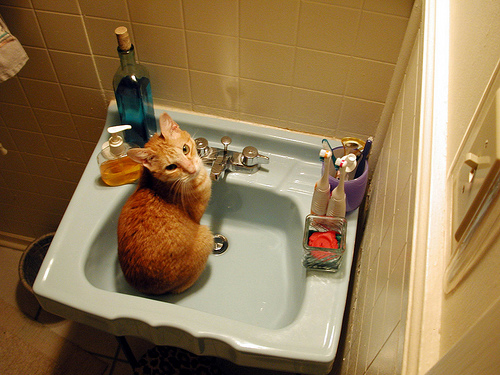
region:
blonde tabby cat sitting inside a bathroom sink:
[117, 111, 212, 296]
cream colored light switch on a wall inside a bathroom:
[455, 98, 496, 240]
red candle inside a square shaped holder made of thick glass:
[302, 212, 347, 272]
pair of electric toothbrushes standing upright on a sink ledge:
[311, 149, 346, 228]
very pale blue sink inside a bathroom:
[31, 96, 364, 372]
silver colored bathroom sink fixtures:
[191, 135, 269, 181]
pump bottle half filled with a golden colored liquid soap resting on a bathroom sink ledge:
[97, 123, 144, 185]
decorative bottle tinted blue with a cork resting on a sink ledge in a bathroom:
[111, 25, 156, 148]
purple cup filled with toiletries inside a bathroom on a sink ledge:
[321, 145, 370, 215]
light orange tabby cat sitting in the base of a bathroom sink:
[116, 111, 211, 296]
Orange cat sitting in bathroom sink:
[114, 112, 216, 297]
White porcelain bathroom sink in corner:
[31, 94, 371, 372]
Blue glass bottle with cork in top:
[111, 24, 158, 151]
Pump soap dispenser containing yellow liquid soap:
[96, 122, 146, 186]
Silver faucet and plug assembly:
[192, 135, 271, 184]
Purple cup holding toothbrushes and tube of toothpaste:
[320, 145, 370, 215]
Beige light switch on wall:
[453, 86, 499, 241]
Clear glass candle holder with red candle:
[301, 213, 349, 274]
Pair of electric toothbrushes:
[310, 148, 349, 220]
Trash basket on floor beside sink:
[18, 228, 58, 296]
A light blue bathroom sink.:
[31, 92, 346, 357]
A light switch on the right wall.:
[442, 85, 495, 240]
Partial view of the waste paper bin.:
[16, 233, 55, 308]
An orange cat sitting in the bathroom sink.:
[116, 108, 211, 292]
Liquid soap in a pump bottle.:
[96, 123, 143, 185]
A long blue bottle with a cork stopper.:
[112, 23, 154, 142]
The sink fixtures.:
[193, 134, 270, 182]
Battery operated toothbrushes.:
[312, 148, 347, 219]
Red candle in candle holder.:
[303, 212, 344, 275]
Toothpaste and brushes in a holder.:
[320, 133, 375, 188]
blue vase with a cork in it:
[112, 27, 153, 145]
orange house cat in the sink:
[117, 113, 212, 293]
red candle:
[307, 230, 337, 262]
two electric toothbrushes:
[310, 147, 350, 218]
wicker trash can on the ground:
[18, 230, 59, 290]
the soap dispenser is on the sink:
[94, 125, 141, 183]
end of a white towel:
[0, 31, 27, 82]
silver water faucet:
[196, 135, 269, 180]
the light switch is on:
[453, 91, 498, 235]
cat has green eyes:
[166, 144, 189, 172]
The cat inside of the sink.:
[122, 110, 209, 302]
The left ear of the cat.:
[124, 146, 151, 164]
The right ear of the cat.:
[155, 114, 180, 138]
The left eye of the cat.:
[165, 163, 177, 171]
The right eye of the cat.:
[179, 143, 191, 155]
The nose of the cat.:
[187, 165, 193, 172]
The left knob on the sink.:
[194, 135, 207, 153]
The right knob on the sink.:
[242, 147, 268, 169]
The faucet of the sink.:
[207, 152, 227, 178]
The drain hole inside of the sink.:
[210, 233, 225, 258]